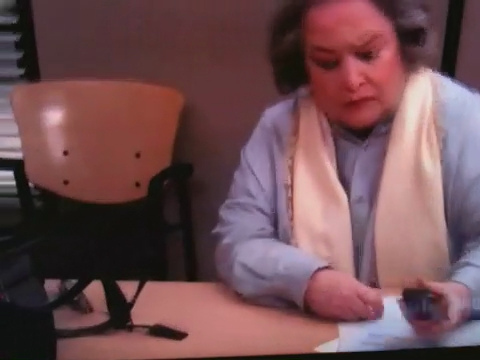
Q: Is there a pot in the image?
A: No, there are no pots.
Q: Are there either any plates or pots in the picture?
A: No, there are no pots or plates.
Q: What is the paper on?
A: The paper is on the table.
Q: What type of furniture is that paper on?
A: The paper is on the table.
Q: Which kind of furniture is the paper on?
A: The paper is on the table.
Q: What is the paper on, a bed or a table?
A: The paper is on a table.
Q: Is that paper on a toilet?
A: No, the paper is on the table.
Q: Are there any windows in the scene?
A: Yes, there is a window.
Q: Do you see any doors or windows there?
A: Yes, there is a window.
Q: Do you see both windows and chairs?
A: Yes, there are both a window and a chair.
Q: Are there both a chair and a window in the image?
A: Yes, there are both a window and a chair.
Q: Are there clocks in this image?
A: No, there are no clocks.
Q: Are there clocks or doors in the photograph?
A: No, there are no clocks or doors.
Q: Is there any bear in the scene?
A: No, there are no bears.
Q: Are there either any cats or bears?
A: No, there are no bears or cats.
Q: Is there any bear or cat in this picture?
A: No, there are no bears or cats.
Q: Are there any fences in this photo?
A: No, there are no fences.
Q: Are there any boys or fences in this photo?
A: No, there are no fences or boys.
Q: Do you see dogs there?
A: No, there are no dogs.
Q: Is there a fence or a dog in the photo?
A: No, there are no dogs or fences.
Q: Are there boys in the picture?
A: No, there are no boys.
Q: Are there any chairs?
A: Yes, there is a chair.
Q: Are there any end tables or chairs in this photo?
A: Yes, there is a chair.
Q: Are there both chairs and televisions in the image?
A: No, there is a chair but no televisions.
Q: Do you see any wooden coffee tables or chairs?
A: Yes, there is a wood chair.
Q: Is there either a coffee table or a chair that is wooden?
A: Yes, the chair is wooden.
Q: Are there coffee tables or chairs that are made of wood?
A: Yes, the chair is made of wood.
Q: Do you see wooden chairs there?
A: Yes, there is a wood chair.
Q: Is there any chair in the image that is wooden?
A: Yes, there is a chair that is wooden.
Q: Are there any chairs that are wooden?
A: Yes, there is a chair that is wooden.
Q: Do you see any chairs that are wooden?
A: Yes, there is a chair that is wooden.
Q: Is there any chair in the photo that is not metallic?
A: Yes, there is a wooden chair.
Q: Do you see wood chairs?
A: Yes, there is a chair that is made of wood.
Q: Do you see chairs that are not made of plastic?
A: Yes, there is a chair that is made of wood.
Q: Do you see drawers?
A: No, there are no drawers.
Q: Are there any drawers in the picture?
A: No, there are no drawers.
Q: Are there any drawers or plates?
A: No, there are no drawers or plates.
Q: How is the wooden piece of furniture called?
A: The piece of furniture is a chair.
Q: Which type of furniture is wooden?
A: The furniture is a chair.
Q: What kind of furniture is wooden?
A: The furniture is a chair.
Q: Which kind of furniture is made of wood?
A: The furniture is a chair.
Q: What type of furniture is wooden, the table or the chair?
A: The chair is wooden.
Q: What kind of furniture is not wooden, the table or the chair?
A: The table is not wooden.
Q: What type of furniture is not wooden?
A: The furniture is a table.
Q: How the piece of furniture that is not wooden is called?
A: The piece of furniture is a table.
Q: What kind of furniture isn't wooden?
A: The furniture is a table.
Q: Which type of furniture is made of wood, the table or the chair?
A: The chair is made of wood.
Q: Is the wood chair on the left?
A: Yes, the chair is on the left of the image.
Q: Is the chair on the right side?
A: No, the chair is on the left of the image.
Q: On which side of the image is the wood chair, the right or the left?
A: The chair is on the left of the image.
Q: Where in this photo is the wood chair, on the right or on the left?
A: The chair is on the left of the image.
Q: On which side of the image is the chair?
A: The chair is on the left of the image.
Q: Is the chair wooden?
A: Yes, the chair is wooden.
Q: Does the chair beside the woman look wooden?
A: Yes, the chair is wooden.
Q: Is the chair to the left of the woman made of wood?
A: Yes, the chair is made of wood.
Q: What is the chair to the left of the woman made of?
A: The chair is made of wood.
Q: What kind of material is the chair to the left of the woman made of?
A: The chair is made of wood.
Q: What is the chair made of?
A: The chair is made of wood.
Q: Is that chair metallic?
A: No, the chair is wooden.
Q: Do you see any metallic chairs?
A: No, there is a chair but it is wooden.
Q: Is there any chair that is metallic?
A: No, there is a chair but it is wooden.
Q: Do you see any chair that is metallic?
A: No, there is a chair but it is wooden.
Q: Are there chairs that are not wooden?
A: No, there is a chair but it is wooden.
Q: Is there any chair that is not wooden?
A: No, there is a chair but it is wooden.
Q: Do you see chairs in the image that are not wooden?
A: No, there is a chair but it is wooden.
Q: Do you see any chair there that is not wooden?
A: No, there is a chair but it is wooden.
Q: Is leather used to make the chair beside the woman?
A: No, the chair is made of wood.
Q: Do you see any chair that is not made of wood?
A: No, there is a chair but it is made of wood.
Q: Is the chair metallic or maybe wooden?
A: The chair is wooden.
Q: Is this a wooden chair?
A: Yes, this is a wooden chair.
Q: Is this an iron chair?
A: No, this is a wooden chair.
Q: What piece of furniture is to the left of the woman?
A: The piece of furniture is a chair.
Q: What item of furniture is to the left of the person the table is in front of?
A: The piece of furniture is a chair.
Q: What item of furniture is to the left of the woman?
A: The piece of furniture is a chair.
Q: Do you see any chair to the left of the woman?
A: Yes, there is a chair to the left of the woman.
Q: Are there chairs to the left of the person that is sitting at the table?
A: Yes, there is a chair to the left of the woman.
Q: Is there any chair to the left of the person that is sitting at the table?
A: Yes, there is a chair to the left of the woman.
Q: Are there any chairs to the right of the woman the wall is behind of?
A: No, the chair is to the left of the woman.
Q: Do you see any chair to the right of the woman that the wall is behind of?
A: No, the chair is to the left of the woman.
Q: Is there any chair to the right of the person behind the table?
A: No, the chair is to the left of the woman.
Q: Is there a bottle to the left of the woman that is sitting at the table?
A: No, there is a chair to the left of the woman.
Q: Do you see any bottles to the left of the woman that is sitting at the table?
A: No, there is a chair to the left of the woman.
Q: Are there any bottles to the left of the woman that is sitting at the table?
A: No, there is a chair to the left of the woman.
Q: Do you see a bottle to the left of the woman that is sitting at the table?
A: No, there is a chair to the left of the woman.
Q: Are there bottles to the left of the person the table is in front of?
A: No, there is a chair to the left of the woman.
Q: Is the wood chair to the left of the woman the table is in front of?
A: Yes, the chair is to the left of the woman.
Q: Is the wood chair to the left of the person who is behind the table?
A: Yes, the chair is to the left of the woman.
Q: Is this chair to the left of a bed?
A: No, the chair is to the left of the woman.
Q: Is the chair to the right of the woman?
A: No, the chair is to the left of the woman.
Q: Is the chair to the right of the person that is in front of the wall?
A: No, the chair is to the left of the woman.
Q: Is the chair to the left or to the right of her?
A: The chair is to the left of the woman.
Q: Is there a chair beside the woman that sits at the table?
A: Yes, there is a chair beside the woman.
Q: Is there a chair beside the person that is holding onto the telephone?
A: Yes, there is a chair beside the woman.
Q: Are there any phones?
A: Yes, there is a phone.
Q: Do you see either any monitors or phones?
A: Yes, there is a phone.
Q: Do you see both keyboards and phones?
A: No, there is a phone but no keyboards.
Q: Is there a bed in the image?
A: No, there are no beds.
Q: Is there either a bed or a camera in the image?
A: No, there are no beds or cameras.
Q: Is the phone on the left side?
A: No, the phone is on the right of the image.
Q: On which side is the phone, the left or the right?
A: The phone is on the right of the image.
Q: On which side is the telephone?
A: The telephone is on the right of the image.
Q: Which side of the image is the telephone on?
A: The telephone is on the right of the image.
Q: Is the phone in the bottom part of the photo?
A: Yes, the phone is in the bottom of the image.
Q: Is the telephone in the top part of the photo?
A: No, the telephone is in the bottom of the image.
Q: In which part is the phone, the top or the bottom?
A: The phone is in the bottom of the image.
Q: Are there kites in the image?
A: No, there are no kites.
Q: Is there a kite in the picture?
A: No, there are no kites.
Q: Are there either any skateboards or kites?
A: No, there are no kites or skateboards.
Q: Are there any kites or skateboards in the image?
A: No, there are no kites or skateboards.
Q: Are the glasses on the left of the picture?
A: Yes, the glasses are on the left of the image.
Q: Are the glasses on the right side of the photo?
A: No, the glasses are on the left of the image.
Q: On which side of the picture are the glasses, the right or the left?
A: The glasses are on the left of the image.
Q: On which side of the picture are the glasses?
A: The glasses are on the left of the image.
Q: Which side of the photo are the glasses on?
A: The glasses are on the left of the image.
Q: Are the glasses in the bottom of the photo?
A: Yes, the glasses are in the bottom of the image.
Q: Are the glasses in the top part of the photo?
A: No, the glasses are in the bottom of the image.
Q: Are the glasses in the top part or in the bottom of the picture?
A: The glasses are in the bottom of the image.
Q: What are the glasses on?
A: The glasses are on the table.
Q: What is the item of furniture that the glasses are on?
A: The piece of furniture is a table.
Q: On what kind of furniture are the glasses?
A: The glasses are on the table.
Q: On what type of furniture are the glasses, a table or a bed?
A: The glasses are on a table.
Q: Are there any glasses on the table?
A: Yes, there are glasses on the table.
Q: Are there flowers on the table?
A: No, there are glasses on the table.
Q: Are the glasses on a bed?
A: No, the glasses are on the table.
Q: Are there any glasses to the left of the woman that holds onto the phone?
A: Yes, there are glasses to the left of the woman.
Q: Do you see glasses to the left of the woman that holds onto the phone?
A: Yes, there are glasses to the left of the woman.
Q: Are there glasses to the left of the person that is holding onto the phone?
A: Yes, there are glasses to the left of the woman.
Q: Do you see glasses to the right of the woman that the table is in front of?
A: No, the glasses are to the left of the woman.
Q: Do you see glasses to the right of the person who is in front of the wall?
A: No, the glasses are to the left of the woman.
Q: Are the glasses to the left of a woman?
A: Yes, the glasses are to the left of a woman.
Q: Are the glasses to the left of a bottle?
A: No, the glasses are to the left of a woman.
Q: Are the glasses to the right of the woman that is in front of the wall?
A: No, the glasses are to the left of the woman.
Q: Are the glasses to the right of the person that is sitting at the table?
A: No, the glasses are to the left of the woman.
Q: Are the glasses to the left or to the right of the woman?
A: The glasses are to the left of the woman.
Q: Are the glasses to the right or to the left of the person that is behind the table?
A: The glasses are to the left of the woman.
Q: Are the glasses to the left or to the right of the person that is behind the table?
A: The glasses are to the left of the woman.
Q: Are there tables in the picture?
A: Yes, there is a table.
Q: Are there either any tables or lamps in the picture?
A: Yes, there is a table.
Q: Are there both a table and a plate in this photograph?
A: No, there is a table but no plates.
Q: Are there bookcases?
A: No, there are no bookcases.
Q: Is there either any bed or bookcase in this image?
A: No, there are no bookcases or beds.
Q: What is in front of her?
A: The table is in front of the woman.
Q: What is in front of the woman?
A: The table is in front of the woman.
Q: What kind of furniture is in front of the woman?
A: The piece of furniture is a table.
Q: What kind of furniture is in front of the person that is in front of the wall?
A: The piece of furniture is a table.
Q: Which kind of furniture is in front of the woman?
A: The piece of furniture is a table.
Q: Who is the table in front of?
A: The table is in front of the woman.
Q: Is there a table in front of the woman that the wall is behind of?
A: Yes, there is a table in front of the woman.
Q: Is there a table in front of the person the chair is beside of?
A: Yes, there is a table in front of the woman.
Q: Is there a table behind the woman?
A: No, the table is in front of the woman.